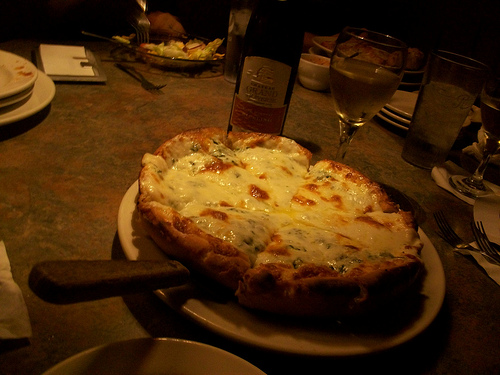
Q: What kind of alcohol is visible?
A: Wine.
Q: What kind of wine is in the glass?
A: White wine.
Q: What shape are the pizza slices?
A: Triangular.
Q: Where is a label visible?
A: On the wine bottle.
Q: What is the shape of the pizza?
A: Round.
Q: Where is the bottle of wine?
A: Behind pizza.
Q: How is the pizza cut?
A: Into triangles.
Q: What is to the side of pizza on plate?
A: Wood handle.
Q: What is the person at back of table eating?
A: A salad.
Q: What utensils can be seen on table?
A: Forks.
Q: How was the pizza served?
A: On a plate.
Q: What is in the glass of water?
A: Ice.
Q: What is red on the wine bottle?
A: Label.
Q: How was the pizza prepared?
A: Deep dish in oven.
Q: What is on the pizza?
A: The cheese topping.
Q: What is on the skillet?
A: The handle.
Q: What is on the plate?
A: The pan of pizza.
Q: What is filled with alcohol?
A: The glass.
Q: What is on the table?
A: The bottle of alcohol.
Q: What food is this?
A: Pizza.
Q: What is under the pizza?
A: Serving tool.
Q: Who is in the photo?
A: No one.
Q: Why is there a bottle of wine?
A: To drink.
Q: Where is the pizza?
A: On a plate.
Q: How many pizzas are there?
A: One.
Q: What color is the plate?
A: White.